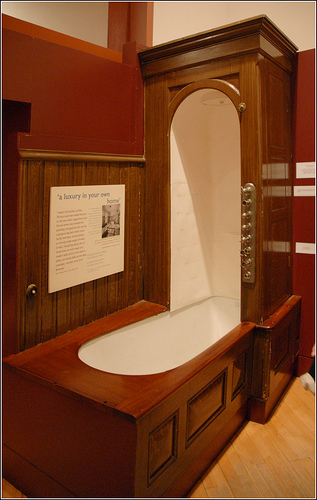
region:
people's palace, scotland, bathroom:
[3, 0, 315, 497]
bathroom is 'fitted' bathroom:
[1, 9, 312, 495]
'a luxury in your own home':
[46, 183, 127, 208]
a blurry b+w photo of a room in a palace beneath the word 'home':
[99, 201, 121, 238]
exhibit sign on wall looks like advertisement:
[44, 180, 126, 294]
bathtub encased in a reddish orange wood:
[3, 292, 314, 494]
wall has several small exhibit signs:
[290, 157, 313, 256]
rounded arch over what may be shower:
[166, 71, 241, 130]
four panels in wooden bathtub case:
[139, 325, 290, 482]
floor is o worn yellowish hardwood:
[3, 374, 315, 497]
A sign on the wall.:
[46, 183, 125, 293]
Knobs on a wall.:
[239, 181, 256, 283]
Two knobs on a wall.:
[239, 182, 255, 206]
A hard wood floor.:
[1, 374, 316, 497]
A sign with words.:
[47, 183, 125, 292]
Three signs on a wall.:
[293, 160, 316, 253]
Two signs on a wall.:
[292, 161, 315, 196]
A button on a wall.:
[25, 283, 38, 298]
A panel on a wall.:
[146, 409, 179, 487]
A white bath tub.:
[76, 294, 240, 375]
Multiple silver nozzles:
[235, 178, 264, 302]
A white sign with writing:
[45, 182, 139, 295]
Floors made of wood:
[239, 379, 309, 477]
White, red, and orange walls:
[11, 5, 152, 163]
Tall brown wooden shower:
[142, 37, 299, 367]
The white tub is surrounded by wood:
[3, 313, 271, 488]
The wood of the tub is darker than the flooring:
[147, 296, 288, 497]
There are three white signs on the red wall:
[293, 156, 314, 270]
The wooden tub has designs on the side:
[136, 299, 293, 491]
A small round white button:
[20, 279, 44, 312]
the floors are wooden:
[247, 457, 259, 468]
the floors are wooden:
[231, 470, 241, 477]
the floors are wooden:
[230, 478, 244, 487]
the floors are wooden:
[239, 472, 248, 484]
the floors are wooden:
[252, 469, 265, 483]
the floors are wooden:
[245, 478, 256, 489]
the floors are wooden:
[240, 468, 248, 480]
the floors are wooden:
[282, 460, 292, 472]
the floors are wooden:
[247, 464, 266, 478]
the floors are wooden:
[278, 456, 291, 482]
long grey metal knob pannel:
[239, 183, 257, 285]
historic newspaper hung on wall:
[48, 180, 126, 294]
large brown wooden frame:
[2, 15, 302, 495]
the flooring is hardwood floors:
[2, 374, 316, 498]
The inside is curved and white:
[79, 88, 248, 376]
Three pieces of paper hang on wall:
[292, 156, 316, 255]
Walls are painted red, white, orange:
[1, 2, 315, 374]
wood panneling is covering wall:
[16, 155, 148, 356]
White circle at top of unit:
[199, 90, 236, 109]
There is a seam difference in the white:
[162, 293, 251, 318]